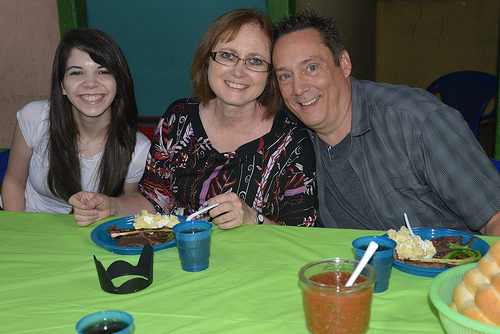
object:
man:
[270, 9, 500, 238]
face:
[64, 50, 116, 117]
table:
[0, 210, 500, 334]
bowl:
[296, 258, 377, 334]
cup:
[172, 219, 213, 271]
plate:
[90, 213, 192, 255]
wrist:
[255, 209, 264, 224]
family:
[0, 8, 500, 237]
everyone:
[0, 10, 500, 237]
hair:
[37, 26, 142, 203]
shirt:
[15, 98, 152, 214]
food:
[105, 209, 181, 247]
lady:
[0, 28, 152, 212]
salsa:
[301, 270, 374, 334]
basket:
[428, 262, 499, 334]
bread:
[449, 241, 500, 326]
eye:
[222, 52, 234, 60]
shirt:
[137, 96, 319, 228]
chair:
[425, 70, 499, 160]